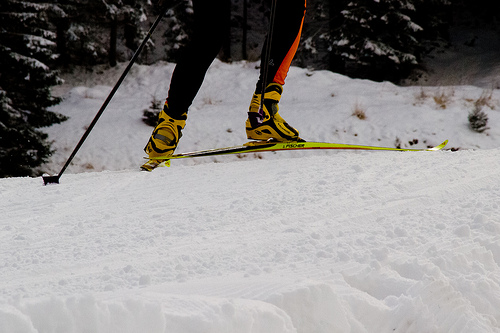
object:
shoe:
[243, 78, 303, 145]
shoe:
[140, 100, 193, 161]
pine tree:
[0, 0, 440, 188]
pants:
[162, 0, 312, 117]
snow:
[30, 34, 56, 50]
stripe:
[268, 3, 310, 87]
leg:
[242, 0, 315, 146]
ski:
[135, 135, 455, 173]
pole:
[38, 0, 175, 188]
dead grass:
[408, 83, 500, 136]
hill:
[39, 42, 458, 153]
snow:
[0, 56, 500, 330]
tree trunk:
[103, 4, 123, 71]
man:
[141, 0, 314, 162]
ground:
[121, 200, 371, 266]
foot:
[141, 100, 194, 167]